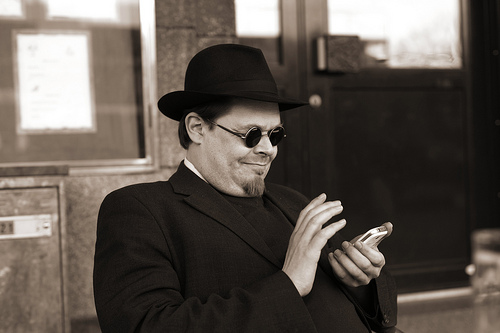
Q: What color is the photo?
A: Black and white.